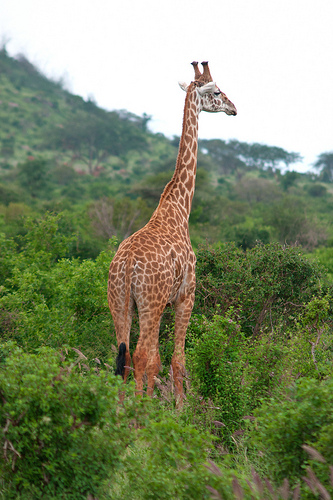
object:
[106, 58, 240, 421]
giraffe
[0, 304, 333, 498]
weeds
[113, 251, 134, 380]
tail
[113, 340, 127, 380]
hair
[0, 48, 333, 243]
terrain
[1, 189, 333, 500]
field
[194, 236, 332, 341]
bushes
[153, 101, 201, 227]
neck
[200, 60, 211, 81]
horns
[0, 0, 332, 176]
sky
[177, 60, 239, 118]
head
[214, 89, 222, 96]
eye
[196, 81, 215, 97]
ears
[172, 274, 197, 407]
leg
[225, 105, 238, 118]
mouth